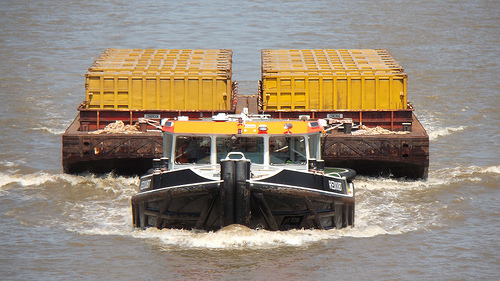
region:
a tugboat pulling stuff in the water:
[141, 122, 361, 242]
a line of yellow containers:
[261, 49, 403, 112]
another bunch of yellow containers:
[83, 42, 234, 114]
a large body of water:
[0, 5, 498, 275]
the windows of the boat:
[176, 135, 311, 168]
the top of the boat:
[161, 117, 323, 135]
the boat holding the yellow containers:
[66, 112, 449, 181]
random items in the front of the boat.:
[88, 113, 398, 138]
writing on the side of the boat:
[325, 177, 347, 192]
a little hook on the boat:
[220, 151, 246, 159]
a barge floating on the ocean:
[64, 114, 446, 173]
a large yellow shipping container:
[86, 47, 248, 114]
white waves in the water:
[197, 228, 280, 244]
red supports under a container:
[80, 103, 122, 133]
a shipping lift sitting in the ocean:
[111, 149, 356, 239]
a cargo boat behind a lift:
[164, 114, 346, 174]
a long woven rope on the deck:
[103, 118, 140, 135]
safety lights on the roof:
[249, 123, 323, 137]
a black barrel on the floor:
[336, 118, 361, 138]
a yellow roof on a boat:
[179, 116, 304, 133]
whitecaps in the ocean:
[10, 166, 60, 191]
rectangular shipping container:
[260, 73, 367, 110]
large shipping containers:
[253, 38, 421, 110]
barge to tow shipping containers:
[137, 123, 354, 235]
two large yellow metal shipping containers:
[73, 37, 415, 120]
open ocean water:
[402, 23, 494, 101]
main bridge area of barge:
[174, 132, 309, 166]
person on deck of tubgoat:
[237, 95, 260, 112]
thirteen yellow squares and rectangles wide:
[262, 76, 413, 113]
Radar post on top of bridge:
[227, 105, 274, 140]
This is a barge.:
[43, 28, 447, 257]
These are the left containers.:
[79, 28, 237, 125]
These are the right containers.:
[241, 27, 441, 135]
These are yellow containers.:
[64, 23, 434, 140]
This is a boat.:
[131, 104, 358, 244]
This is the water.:
[410, 40, 448, 65]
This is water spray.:
[211, 230, 248, 240]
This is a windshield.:
[174, 133, 310, 173]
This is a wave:
[437, 148, 491, 197]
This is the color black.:
[284, 171, 298, 180]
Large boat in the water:
[0, 14, 435, 246]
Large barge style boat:
[30, 30, 443, 244]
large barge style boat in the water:
[38, 27, 443, 237]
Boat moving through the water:
[30, 21, 467, 259]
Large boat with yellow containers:
[40, 27, 449, 244]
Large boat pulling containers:
[31, 16, 455, 243]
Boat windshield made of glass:
[165, 131, 309, 169]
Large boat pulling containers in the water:
[37, 19, 442, 245]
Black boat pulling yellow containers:
[41, 23, 454, 245]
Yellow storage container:
[245, 32, 413, 122]